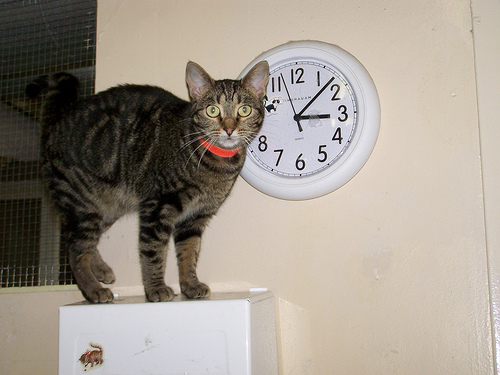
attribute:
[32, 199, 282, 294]
legs — rear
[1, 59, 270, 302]
cat — brown, white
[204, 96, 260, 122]
eyes — green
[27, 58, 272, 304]
cat — gray, black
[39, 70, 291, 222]
cat — grey, black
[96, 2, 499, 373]
wall — white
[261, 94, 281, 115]
dog — black, white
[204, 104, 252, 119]
eyes — yellow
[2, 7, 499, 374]
wall — tan, painted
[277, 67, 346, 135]
hands — black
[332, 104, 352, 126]
three — number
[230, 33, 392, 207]
clock — white